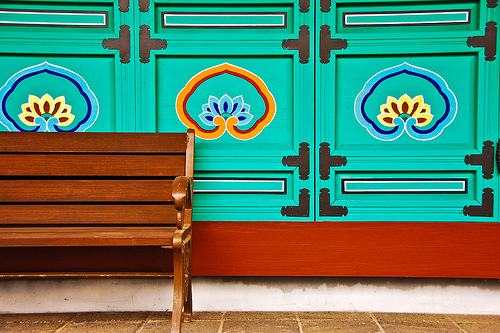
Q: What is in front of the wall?
A: Bench.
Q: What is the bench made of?
A: Wood.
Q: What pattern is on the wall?
A: Flowers.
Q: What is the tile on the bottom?
A: Red.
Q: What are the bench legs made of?
A: Wood.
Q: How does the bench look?
A: Brown.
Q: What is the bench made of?
A: Wood.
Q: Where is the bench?
A: In front of building.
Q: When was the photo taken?
A: Daylight.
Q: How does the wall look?
A: Green with flowers.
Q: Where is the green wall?
A: Behind bench.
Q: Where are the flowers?
A: On wall.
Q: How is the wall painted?
A: Light green.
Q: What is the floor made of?
A: Tiles.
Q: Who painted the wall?
A: A painter.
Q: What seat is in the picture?
A: A bench.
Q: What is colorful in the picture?
A: Aqua wall storage.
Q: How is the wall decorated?
A: In aqua, orange and blue.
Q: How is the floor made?
A: Of tile.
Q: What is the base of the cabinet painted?
A: Orange.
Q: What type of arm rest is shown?
A: Curvy.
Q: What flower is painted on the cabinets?
A: Lotus.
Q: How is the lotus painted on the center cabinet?
A: With orange and red paint.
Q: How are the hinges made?
A: Of iron.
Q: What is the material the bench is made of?
A: Wood.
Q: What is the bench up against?
A: Wall.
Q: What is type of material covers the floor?
A: Tiles.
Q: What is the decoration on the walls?
A: Flowers.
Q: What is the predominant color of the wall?
A: Blue.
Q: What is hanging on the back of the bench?
A: Nothing.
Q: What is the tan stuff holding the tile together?
A: Grout.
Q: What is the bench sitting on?
A: Floor.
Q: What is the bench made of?
A: Wood.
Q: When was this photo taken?
A: Daytime.